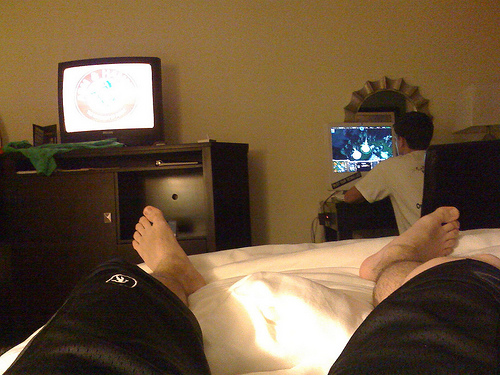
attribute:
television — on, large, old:
[54, 54, 169, 141]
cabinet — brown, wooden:
[5, 145, 253, 336]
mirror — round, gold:
[339, 77, 435, 128]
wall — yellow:
[202, 15, 339, 123]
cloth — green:
[7, 139, 121, 171]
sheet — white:
[192, 241, 371, 374]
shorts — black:
[7, 258, 500, 375]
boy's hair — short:
[394, 112, 439, 149]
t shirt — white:
[354, 146, 429, 233]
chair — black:
[419, 145, 499, 230]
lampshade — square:
[455, 82, 499, 131]